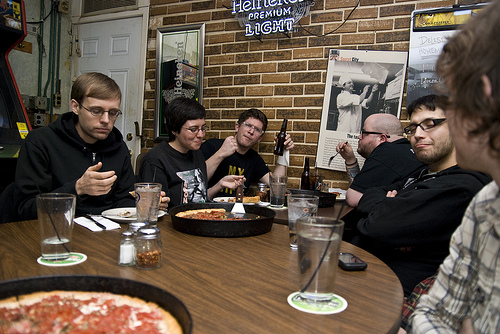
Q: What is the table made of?
A: Wood.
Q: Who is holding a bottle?
A: Guy next to wall on left.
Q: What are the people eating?
A: Pizzas.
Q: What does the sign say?
A: Heineken.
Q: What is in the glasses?
A: Water.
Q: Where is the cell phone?
A: Lying on the table.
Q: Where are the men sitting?
A: At a round table.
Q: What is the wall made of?
A: Brick.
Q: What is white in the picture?
A: Door.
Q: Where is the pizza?
A: In pan.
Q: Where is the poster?
A: On wall.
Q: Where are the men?
A: Around table.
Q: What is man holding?
A: Beer bottle.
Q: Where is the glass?
A: On coaster.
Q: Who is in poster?
A: A man.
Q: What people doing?
A: Sitting.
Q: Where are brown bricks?
A: On the wall.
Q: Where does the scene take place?
A: In a restaurant.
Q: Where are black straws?
A: In glasses.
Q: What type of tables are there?
A: Wooden.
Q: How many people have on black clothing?
A: 5.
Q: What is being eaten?
A: Pizza.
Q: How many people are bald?
A: One.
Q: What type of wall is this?
A: Brick.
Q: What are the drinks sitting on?
A: Coasters.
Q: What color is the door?
A: White.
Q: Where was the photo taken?
A: Restaurant.